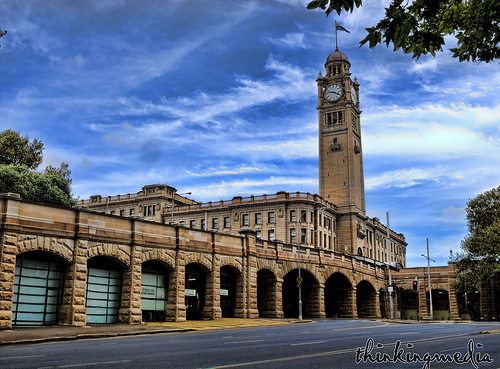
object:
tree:
[0, 128, 76, 208]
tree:
[305, 0, 498, 66]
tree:
[453, 186, 499, 322]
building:
[398, 260, 500, 318]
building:
[311, 20, 409, 319]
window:
[268, 210, 276, 224]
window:
[255, 212, 262, 224]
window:
[242, 214, 249, 227]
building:
[0, 190, 73, 341]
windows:
[324, 109, 344, 130]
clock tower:
[317, 18, 366, 215]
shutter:
[11, 252, 67, 331]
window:
[268, 229, 275, 243]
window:
[242, 211, 250, 226]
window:
[290, 209, 297, 223]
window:
[211, 218, 219, 230]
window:
[129, 207, 135, 219]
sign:
[296, 276, 303, 283]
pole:
[299, 281, 303, 323]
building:
[97, 183, 264, 331]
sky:
[58, 14, 88, 111]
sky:
[399, 66, 499, 180]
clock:
[323, 81, 345, 103]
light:
[421, 237, 435, 321]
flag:
[334, 20, 351, 53]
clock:
[350, 83, 360, 106]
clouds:
[35, 65, 100, 130]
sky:
[201, 18, 276, 129]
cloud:
[158, 80, 313, 152]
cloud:
[388, 92, 489, 169]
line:
[212, 331, 472, 368]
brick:
[321, 158, 347, 175]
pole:
[420, 238, 436, 320]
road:
[0, 318, 500, 369]